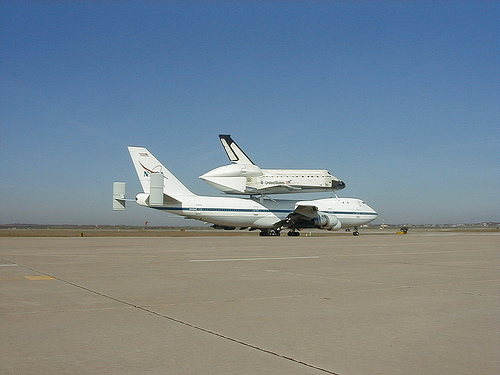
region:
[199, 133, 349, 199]
a United States Space Shuttle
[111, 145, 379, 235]
a white NASA airplane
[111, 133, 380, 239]
Space Shuttle being carried on airplane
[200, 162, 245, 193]
white tail cone protector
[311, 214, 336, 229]
airplane jet engine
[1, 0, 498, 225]
a clear blue sky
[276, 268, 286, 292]
the view of a white wall and chairs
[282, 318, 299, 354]
the view of a white wall and chairs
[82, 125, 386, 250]
white plane with shuttle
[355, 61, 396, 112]
white clouds in blue sky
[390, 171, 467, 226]
white clouds in blue sky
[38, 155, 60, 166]
white clouds in blue sky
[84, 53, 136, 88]
white clouds in blue sky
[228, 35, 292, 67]
white clouds in blue sky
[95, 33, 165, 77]
white clouds in blue sky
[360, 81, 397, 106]
white clouds in blue sky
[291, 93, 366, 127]
white clouds in blue sky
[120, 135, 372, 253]
white plane and shuttle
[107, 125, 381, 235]
A plane with another plane on top of it.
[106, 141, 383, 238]
A plane owned by NASA.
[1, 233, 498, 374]
A runway for planes.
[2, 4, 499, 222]
A cloudless blue sky.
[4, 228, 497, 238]
A strip of grass on the far side of the runway.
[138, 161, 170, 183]
NASA logo, blocked by part of the plane.